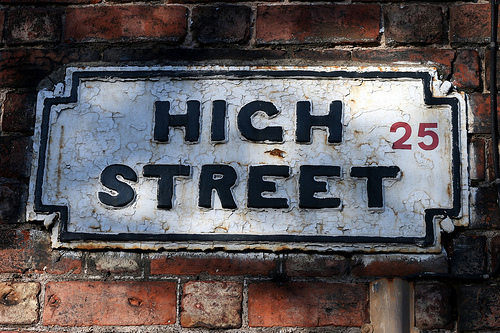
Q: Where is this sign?
A: High Street.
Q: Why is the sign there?
A: So people know where they are.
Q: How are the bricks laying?
A: Stacked.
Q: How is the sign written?
A: Printed.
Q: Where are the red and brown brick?
A: On the wall.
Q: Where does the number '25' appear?
A: On the sign.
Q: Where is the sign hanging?
A: On the wall.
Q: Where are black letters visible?
A: On the sign.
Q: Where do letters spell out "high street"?
A: On the sign.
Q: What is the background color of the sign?
A: White.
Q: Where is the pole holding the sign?
A: Under the 'T'.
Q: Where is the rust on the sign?
A: Under the paint.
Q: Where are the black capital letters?
A: On the sigh.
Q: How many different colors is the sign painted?
A: Three.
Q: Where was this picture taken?
A: High street.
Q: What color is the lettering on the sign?
A: Black.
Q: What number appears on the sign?
A: 25.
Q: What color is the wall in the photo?
A: Red.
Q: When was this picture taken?
A: Daytime.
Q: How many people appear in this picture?
A: Zero.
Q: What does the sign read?
A: High Street.